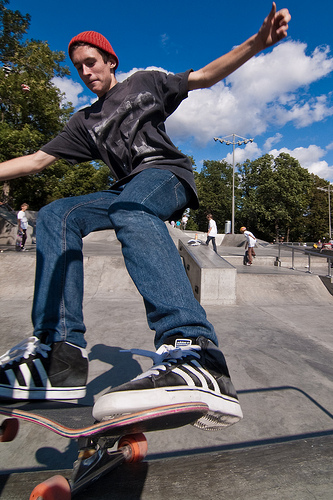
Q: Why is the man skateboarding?
A: Recreation.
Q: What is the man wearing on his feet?
A: Sneakers.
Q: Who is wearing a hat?
A: The skateboarder.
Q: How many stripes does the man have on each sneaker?
A: Three.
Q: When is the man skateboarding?
A: Daytime.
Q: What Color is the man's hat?
A: Red.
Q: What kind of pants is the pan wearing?
A: Blue jeans.